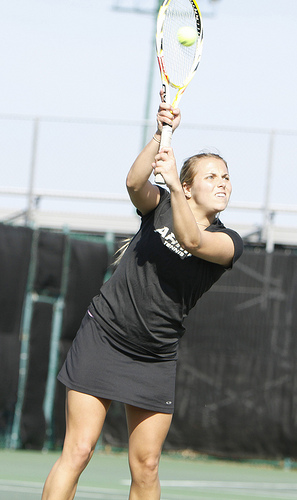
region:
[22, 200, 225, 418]
lady is in black dress.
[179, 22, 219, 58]
ball is green in color.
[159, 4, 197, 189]
bat is mainly white in color.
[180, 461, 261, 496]
ground is green in color.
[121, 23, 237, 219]
lady is playing tennis.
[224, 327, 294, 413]
screen is black in color.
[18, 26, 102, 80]
sky is white in color.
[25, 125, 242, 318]
day is sunny.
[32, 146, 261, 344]
daytime picture.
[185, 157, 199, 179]
hair is blonde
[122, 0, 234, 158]
the lady is holding a tennis racket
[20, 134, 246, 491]
the lady is wearing clothes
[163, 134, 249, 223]
the lady has brown hair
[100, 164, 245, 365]
the lady is wearing black tshirt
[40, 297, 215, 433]
the lady is wearing a black miniskirt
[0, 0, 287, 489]
the photo was taken outdoors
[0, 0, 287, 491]
the photo was taken durig the day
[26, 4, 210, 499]
the lady is an adult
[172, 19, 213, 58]
the tennis ball is green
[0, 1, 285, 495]
the lady is alone in the photo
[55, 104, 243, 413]
The female tennis player wearing black.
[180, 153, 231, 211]
The woman making a face.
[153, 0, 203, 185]
Her hands holding the tennis racket.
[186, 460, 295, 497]
The green ground of the tennis court.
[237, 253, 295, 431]
The black covered wall.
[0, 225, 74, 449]
Blue-green colored poles.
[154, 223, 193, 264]
The writing on her black shirt.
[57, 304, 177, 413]
Her short black skirt.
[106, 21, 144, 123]
The pale sky above.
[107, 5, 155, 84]
Part of the blue-green structure.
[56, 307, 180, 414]
a short black skirt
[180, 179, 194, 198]
a woman's right ear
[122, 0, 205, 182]
a tennis racket hitting a ball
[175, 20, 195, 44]
a yellow tennis ball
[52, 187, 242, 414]
a black skirt and top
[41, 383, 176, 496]
a pair of nice legs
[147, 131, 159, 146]
a beautiful piece of jewelry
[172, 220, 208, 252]
a woman's bent elbow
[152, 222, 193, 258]
white lettering on a black shirt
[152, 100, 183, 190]
two hands gripping a tennis racket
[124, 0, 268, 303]
a grimace accompanying a collision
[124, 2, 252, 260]
a two hand overhand volley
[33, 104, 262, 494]
female in black on black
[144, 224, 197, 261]
wearing a logo for a fee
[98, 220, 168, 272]
long blonde hair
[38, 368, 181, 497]
some muscle in these quads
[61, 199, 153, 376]
not an hourglass figure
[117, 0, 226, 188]
a colorful tennis racket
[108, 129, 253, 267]
girl with hair slicked back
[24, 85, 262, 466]
tennis player dressed in black